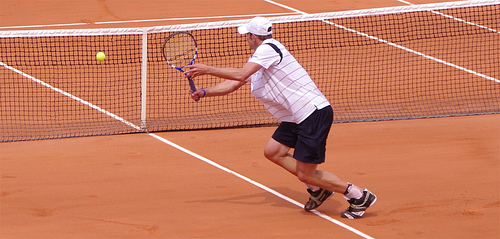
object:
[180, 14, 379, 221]
man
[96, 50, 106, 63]
tennis ball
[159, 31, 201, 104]
tennis racket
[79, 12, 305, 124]
tennis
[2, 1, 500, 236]
tennis court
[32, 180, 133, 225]
clay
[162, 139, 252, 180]
painted lines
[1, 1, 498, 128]
tennis net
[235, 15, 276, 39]
white hat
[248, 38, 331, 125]
striped shirt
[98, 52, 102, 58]
yellow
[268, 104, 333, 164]
navy blue shorts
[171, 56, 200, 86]
black and blue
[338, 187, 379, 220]
tennis shoes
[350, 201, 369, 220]
white and blue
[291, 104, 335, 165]
black shorts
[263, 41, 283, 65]
stripes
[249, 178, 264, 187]
white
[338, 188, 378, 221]
left foot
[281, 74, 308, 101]
thin black stripes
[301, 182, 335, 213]
right foot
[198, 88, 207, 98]
blue bracelet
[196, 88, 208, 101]
wrist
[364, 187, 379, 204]
black and white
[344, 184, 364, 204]
socks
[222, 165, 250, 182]
are white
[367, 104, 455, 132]
ground